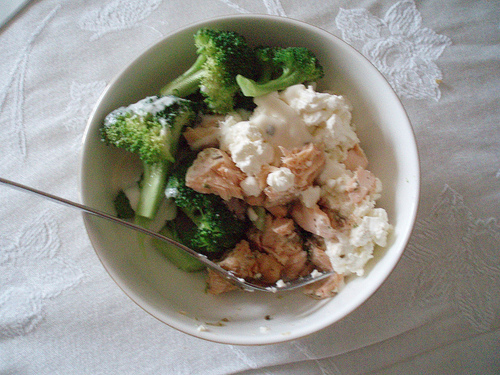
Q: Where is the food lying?
A: Bowl.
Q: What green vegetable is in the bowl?
A: Broccoli.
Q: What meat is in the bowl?
A: Chicken.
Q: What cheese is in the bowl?
A: Feta.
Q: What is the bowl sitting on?
A: A table.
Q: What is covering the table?
A: A tablecloth.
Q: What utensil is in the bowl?
A: A fork.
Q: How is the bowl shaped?
A: Roundly.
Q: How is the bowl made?
A: Of ceramic.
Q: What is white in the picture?
A: Bowl and tablecloth.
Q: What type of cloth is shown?
A: Damask.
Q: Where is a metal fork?
A: In the bowl.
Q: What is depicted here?
A: A piece of broccoli.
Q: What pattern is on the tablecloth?
A: A white floral pattern.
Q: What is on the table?
A: A white bowl.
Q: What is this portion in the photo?
A: The handle of a fork.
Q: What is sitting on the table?
A: A bowl full of food.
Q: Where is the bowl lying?
A: On top of table cloth.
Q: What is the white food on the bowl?
A: Cheese with dressing.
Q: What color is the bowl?
A: White.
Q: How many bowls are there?
A: One.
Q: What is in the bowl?
A: Food.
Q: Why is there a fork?
A: To eat the food.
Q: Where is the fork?
A: In the bowl.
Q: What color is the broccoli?
A: Green.